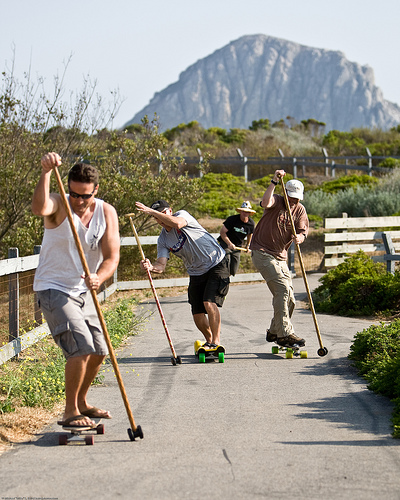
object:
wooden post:
[7, 242, 27, 351]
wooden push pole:
[126, 211, 184, 365]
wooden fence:
[326, 215, 399, 269]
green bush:
[0, 60, 28, 225]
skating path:
[2, 265, 396, 499]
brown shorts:
[186, 262, 235, 306]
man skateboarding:
[124, 195, 233, 364]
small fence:
[0, 272, 15, 337]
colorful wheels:
[84, 431, 98, 445]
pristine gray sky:
[0, 2, 399, 129]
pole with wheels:
[47, 151, 148, 440]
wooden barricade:
[1, 244, 47, 366]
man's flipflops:
[56, 414, 96, 428]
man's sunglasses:
[154, 205, 171, 217]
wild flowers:
[20, 360, 45, 398]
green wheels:
[217, 354, 224, 362]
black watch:
[269, 176, 279, 183]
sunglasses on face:
[66, 188, 98, 199]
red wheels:
[60, 428, 69, 444]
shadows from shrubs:
[291, 385, 379, 453]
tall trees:
[48, 78, 81, 175]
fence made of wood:
[0, 231, 268, 368]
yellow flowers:
[23, 331, 33, 344]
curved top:
[223, 29, 286, 60]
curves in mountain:
[312, 36, 399, 114]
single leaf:
[152, 136, 165, 144]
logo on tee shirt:
[163, 229, 186, 252]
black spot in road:
[149, 355, 177, 395]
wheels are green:
[195, 350, 207, 364]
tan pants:
[250, 246, 298, 335]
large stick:
[273, 166, 329, 357]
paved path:
[0, 272, 398, 499]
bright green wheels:
[300, 352, 306, 362]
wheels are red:
[99, 423, 106, 431]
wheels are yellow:
[283, 348, 292, 359]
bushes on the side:
[360, 312, 398, 378]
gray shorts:
[34, 286, 112, 360]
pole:
[123, 211, 181, 366]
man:
[38, 160, 119, 427]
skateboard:
[187, 341, 226, 365]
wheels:
[126, 425, 143, 441]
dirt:
[0, 217, 400, 465]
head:
[281, 180, 305, 206]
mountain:
[118, 30, 387, 134]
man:
[253, 169, 311, 346]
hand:
[270, 168, 286, 186]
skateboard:
[58, 408, 103, 446]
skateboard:
[265, 333, 307, 361]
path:
[2, 269, 387, 493]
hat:
[281, 177, 305, 200]